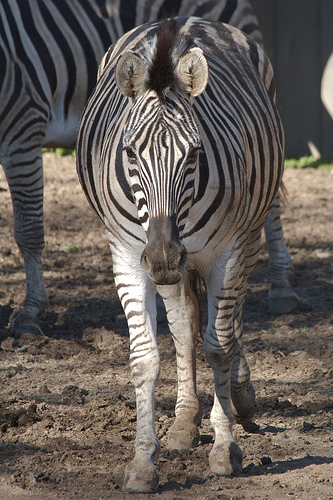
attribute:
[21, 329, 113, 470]
ground — brown, muddy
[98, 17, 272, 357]
zebra — black, striped, tall, standing, strong, mad, white, walking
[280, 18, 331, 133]
fence — black, gray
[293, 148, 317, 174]
grass — green